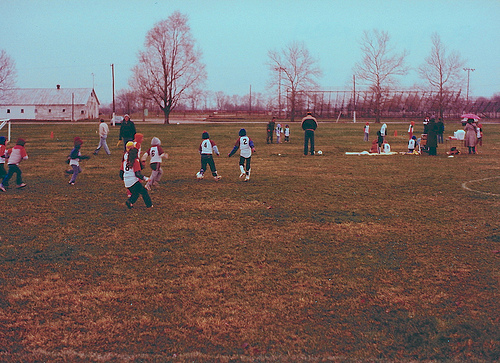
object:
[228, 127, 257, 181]
child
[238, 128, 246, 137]
blue hat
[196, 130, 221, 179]
child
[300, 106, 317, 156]
man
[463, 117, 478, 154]
woman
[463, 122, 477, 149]
dress jacket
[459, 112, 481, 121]
umbrella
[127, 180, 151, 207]
pants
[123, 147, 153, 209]
girl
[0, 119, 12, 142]
net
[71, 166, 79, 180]
pants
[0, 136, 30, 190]
child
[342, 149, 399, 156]
blanket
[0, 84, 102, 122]
barn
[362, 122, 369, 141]
person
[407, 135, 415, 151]
person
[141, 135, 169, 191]
person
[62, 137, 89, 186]
person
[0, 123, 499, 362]
soccer field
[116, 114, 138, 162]
adult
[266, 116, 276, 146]
man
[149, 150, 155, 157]
6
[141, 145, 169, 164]
shirt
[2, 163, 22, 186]
child jeans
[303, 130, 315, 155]
pants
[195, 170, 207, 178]
soccer ball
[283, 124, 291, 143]
child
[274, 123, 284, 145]
child